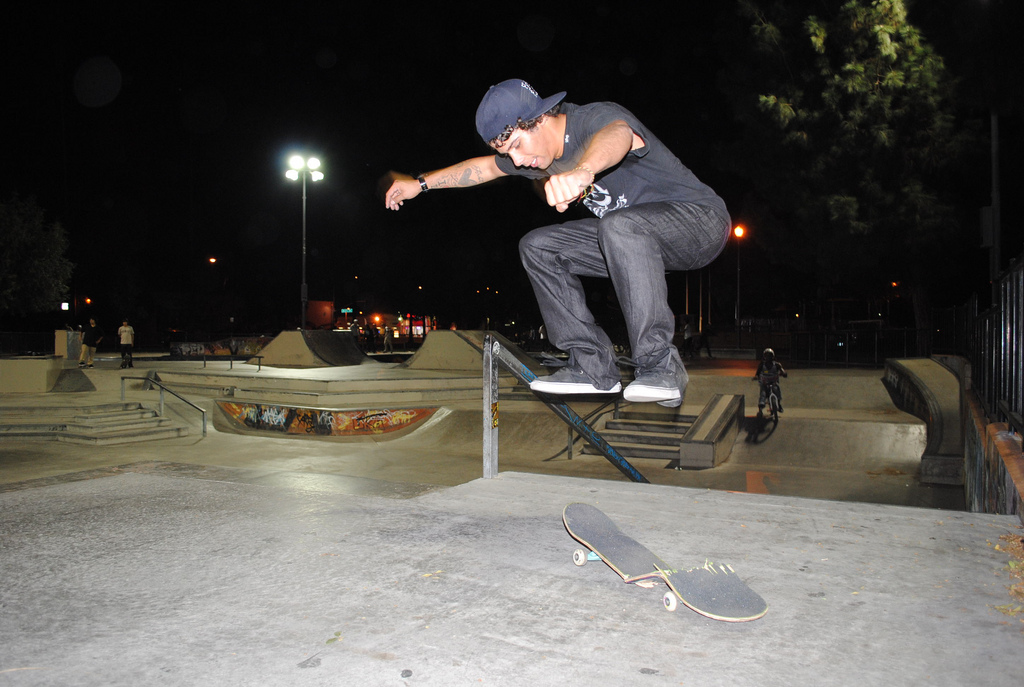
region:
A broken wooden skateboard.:
[560, 496, 767, 621]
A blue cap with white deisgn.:
[473, 75, 563, 142]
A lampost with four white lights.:
[279, 152, 328, 330]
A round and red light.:
[727, 224, 756, 240]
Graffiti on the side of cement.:
[210, 396, 433, 439]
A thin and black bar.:
[115, 372, 208, 430]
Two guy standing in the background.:
[68, 313, 138, 367]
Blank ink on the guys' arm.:
[427, 162, 489, 192]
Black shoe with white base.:
[526, 370, 622, 394]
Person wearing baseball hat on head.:
[468, 73, 561, 132]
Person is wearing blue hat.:
[460, 70, 581, 135]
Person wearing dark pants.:
[525, 211, 729, 361]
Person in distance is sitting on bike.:
[755, 344, 806, 418]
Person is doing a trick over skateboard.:
[363, 70, 744, 441]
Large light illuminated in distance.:
[271, 136, 342, 264]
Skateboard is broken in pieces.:
[612, 533, 762, 633]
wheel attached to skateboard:
[654, 597, 680, 610]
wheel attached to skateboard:
[569, 547, 586, 570]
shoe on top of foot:
[614, 373, 681, 408]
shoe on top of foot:
[531, 368, 633, 410]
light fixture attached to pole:
[269, 147, 334, 186]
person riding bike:
[742, 343, 800, 419]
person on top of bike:
[750, 345, 793, 393]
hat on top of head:
[468, 82, 590, 144]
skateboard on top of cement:
[557, 496, 777, 629]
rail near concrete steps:
[115, 371, 214, 436]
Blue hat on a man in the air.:
[476, 75, 568, 143]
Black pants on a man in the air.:
[518, 199, 734, 390]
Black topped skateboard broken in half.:
[562, 502, 769, 621]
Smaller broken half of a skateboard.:
[654, 564, 768, 626]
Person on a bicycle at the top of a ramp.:
[752, 343, 785, 414]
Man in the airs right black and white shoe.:
[528, 363, 623, 396]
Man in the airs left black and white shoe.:
[622, 373, 683, 406]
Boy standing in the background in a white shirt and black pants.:
[114, 316, 135, 370]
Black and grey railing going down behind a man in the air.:
[482, 333, 651, 488]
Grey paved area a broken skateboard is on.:
[3, 471, 1022, 684]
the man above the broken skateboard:
[384, 75, 770, 626]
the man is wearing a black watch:
[384, 79, 730, 406]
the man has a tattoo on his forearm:
[384, 78, 730, 412]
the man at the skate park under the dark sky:
[1, 2, 1022, 682]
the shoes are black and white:
[528, 360, 681, 403]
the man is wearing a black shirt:
[381, 76, 730, 412]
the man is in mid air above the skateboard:
[380, 78, 767, 623]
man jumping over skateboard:
[358, 69, 739, 424]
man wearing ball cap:
[459, 62, 567, 142]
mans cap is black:
[465, 69, 577, 149]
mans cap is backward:
[465, 69, 574, 156]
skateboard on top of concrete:
[553, 492, 769, 633]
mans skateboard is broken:
[560, 486, 764, 632]